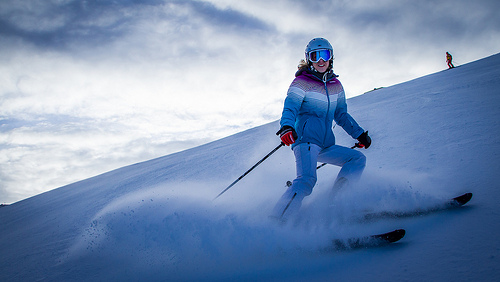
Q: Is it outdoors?
A: Yes, it is outdoors.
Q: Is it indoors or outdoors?
A: It is outdoors.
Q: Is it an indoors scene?
A: No, it is outdoors.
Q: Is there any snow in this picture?
A: Yes, there is snow.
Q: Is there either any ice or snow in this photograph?
A: Yes, there is snow.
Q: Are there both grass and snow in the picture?
A: No, there is snow but no grass.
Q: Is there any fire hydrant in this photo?
A: No, there are no fire hydrants.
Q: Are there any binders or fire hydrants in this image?
A: No, there are no fire hydrants or binders.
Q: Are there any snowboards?
A: No, there are no snowboards.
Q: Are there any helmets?
A: Yes, there is a helmet.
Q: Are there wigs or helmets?
A: Yes, there is a helmet.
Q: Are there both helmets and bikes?
A: No, there is a helmet but no bikes.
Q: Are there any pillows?
A: No, there are no pillows.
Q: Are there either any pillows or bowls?
A: No, there are no pillows or bowls.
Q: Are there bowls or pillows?
A: No, there are no pillows or bowls.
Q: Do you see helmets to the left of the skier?
A: Yes, there is a helmet to the left of the skier.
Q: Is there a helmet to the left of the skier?
A: Yes, there is a helmet to the left of the skier.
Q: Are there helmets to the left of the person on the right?
A: Yes, there is a helmet to the left of the skier.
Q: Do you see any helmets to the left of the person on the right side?
A: Yes, there is a helmet to the left of the skier.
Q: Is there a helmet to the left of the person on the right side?
A: Yes, there is a helmet to the left of the skier.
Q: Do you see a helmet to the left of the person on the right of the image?
A: Yes, there is a helmet to the left of the skier.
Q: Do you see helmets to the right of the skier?
A: No, the helmet is to the left of the skier.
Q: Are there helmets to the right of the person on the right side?
A: No, the helmet is to the left of the skier.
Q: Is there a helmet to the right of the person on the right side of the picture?
A: No, the helmet is to the left of the skier.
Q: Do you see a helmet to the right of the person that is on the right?
A: No, the helmet is to the left of the skier.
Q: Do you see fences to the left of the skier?
A: No, there is a helmet to the left of the skier.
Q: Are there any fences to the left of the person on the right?
A: No, there is a helmet to the left of the skier.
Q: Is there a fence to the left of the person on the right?
A: No, there is a helmet to the left of the skier.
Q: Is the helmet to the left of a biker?
A: No, the helmet is to the left of a skier.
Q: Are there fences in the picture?
A: No, there are no fences.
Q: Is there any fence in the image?
A: No, there are no fences.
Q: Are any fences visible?
A: No, there are no fences.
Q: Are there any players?
A: No, there are no players.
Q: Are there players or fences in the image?
A: No, there are no players or fences.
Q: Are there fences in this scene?
A: No, there are no fences.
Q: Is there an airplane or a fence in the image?
A: No, there are no fences or airplanes.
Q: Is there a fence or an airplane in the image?
A: No, there are no fences or airplanes.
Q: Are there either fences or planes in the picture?
A: No, there are no fences or planes.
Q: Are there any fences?
A: No, there are no fences.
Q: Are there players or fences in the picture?
A: No, there are no fences or players.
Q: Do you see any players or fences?
A: No, there are no fences or players.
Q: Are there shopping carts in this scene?
A: No, there are no shopping carts.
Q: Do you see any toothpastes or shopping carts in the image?
A: No, there are no shopping carts or toothpastes.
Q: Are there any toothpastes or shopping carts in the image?
A: No, there are no shopping carts or toothpastes.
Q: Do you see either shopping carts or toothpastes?
A: No, there are no shopping carts or toothpastes.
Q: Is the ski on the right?
A: Yes, the ski is on the right of the image.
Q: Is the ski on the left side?
A: No, the ski is on the right of the image.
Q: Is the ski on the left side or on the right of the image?
A: The ski is on the right of the image.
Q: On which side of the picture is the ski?
A: The ski is on the right of the image.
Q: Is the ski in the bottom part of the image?
A: Yes, the ski is in the bottom of the image.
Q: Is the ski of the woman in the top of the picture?
A: No, the ski is in the bottom of the image.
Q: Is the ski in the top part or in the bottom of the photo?
A: The ski is in the bottom of the image.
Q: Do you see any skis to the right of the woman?
A: Yes, there is a ski to the right of the woman.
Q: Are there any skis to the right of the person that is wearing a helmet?
A: Yes, there is a ski to the right of the woman.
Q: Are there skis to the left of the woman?
A: No, the ski is to the right of the woman.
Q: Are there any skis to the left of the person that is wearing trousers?
A: No, the ski is to the right of the woman.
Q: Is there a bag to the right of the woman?
A: No, there is a ski to the right of the woman.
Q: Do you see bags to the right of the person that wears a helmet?
A: No, there is a ski to the right of the woman.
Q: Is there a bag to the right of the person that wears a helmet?
A: No, there is a ski to the right of the woman.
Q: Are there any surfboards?
A: No, there are no surfboards.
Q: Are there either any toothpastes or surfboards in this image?
A: No, there are no surfboards or toothpastes.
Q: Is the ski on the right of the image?
A: Yes, the ski is on the right of the image.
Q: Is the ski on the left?
A: No, the ski is on the right of the image.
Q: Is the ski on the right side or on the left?
A: The ski is on the right of the image.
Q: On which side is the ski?
A: The ski is on the right of the image.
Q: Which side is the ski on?
A: The ski is on the right of the image.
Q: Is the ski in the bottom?
A: Yes, the ski is in the bottom of the image.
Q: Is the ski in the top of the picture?
A: No, the ski is in the bottom of the image.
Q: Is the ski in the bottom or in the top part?
A: The ski is in the bottom of the image.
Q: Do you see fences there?
A: No, there are no fences.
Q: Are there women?
A: Yes, there is a woman.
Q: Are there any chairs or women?
A: Yes, there is a woman.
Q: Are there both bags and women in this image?
A: No, there is a woman but no bags.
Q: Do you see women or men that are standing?
A: Yes, the woman is standing.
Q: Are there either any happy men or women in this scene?
A: Yes, there is a happy woman.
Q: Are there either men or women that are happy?
A: Yes, the woman is happy.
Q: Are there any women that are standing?
A: Yes, there is a woman that is standing.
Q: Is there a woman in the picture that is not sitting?
A: Yes, there is a woman that is standing.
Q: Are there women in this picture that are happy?
A: Yes, there is a happy woman.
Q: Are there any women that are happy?
A: Yes, there is a woman that is happy.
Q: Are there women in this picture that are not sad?
A: Yes, there is a happy woman.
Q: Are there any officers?
A: No, there are no officers.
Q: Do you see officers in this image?
A: No, there are no officers.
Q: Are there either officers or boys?
A: No, there are no officers or boys.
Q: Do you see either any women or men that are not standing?
A: No, there is a woman but she is standing.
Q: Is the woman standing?
A: Yes, the woman is standing.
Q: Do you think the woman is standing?
A: Yes, the woman is standing.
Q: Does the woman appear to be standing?
A: Yes, the woman is standing.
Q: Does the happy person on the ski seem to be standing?
A: Yes, the woman is standing.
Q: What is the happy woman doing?
A: The woman is standing.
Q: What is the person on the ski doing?
A: The woman is standing.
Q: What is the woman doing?
A: The woman is standing.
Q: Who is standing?
A: The woman is standing.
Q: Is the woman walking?
A: No, the woman is standing.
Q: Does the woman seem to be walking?
A: No, the woman is standing.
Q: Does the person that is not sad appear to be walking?
A: No, the woman is standing.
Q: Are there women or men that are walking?
A: No, there is a woman but she is standing.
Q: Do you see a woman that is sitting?
A: No, there is a woman but she is standing.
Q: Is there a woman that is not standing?
A: No, there is a woman but she is standing.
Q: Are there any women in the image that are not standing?
A: No, there is a woman but she is standing.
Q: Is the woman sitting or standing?
A: The woman is standing.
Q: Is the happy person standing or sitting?
A: The woman is standing.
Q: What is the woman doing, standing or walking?
A: The woman is standing.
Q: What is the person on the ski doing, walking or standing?
A: The woman is standing.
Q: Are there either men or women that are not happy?
A: No, there is a woman but she is happy.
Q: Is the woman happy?
A: Yes, the woman is happy.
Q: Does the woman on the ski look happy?
A: Yes, the woman is happy.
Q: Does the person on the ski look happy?
A: Yes, the woman is happy.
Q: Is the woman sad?
A: No, the woman is happy.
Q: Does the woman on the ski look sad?
A: No, the woman is happy.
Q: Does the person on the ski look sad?
A: No, the woman is happy.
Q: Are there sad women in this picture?
A: No, there is a woman but she is happy.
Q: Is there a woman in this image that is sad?
A: No, there is a woman but she is happy.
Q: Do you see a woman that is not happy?
A: No, there is a woman but she is happy.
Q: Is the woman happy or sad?
A: The woman is happy.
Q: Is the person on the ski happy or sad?
A: The woman is happy.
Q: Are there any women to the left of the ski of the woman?
A: Yes, there is a woman to the left of the ski.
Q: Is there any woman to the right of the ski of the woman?
A: No, the woman is to the left of the ski.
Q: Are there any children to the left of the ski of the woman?
A: No, there is a woman to the left of the ski.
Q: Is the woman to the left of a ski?
A: Yes, the woman is to the left of a ski.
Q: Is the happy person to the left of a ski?
A: Yes, the woman is to the left of a ski.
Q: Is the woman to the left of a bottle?
A: No, the woman is to the left of a ski.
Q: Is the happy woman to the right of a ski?
A: No, the woman is to the left of a ski.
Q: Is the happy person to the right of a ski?
A: No, the woman is to the left of a ski.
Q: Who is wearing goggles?
A: The woman is wearing goggles.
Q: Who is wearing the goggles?
A: The woman is wearing goggles.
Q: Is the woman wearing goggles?
A: Yes, the woman is wearing goggles.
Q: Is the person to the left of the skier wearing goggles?
A: Yes, the woman is wearing goggles.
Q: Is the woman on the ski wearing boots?
A: No, the woman is wearing goggles.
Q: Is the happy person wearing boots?
A: No, the woman is wearing goggles.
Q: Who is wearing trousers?
A: The woman is wearing trousers.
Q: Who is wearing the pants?
A: The woman is wearing trousers.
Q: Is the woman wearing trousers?
A: Yes, the woman is wearing trousers.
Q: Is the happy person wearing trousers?
A: Yes, the woman is wearing trousers.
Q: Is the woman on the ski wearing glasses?
A: No, the woman is wearing trousers.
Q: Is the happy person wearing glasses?
A: No, the woman is wearing trousers.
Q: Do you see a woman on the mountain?
A: Yes, there is a woman on the mountain.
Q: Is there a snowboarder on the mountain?
A: No, there is a woman on the mountain.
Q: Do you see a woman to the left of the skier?
A: Yes, there is a woman to the left of the skier.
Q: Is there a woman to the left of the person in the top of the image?
A: Yes, there is a woman to the left of the skier.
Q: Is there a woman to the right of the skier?
A: No, the woman is to the left of the skier.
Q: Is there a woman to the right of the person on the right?
A: No, the woman is to the left of the skier.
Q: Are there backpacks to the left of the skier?
A: No, there is a woman to the left of the skier.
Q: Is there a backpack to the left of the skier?
A: No, there is a woman to the left of the skier.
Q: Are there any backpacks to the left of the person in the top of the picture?
A: No, there is a woman to the left of the skier.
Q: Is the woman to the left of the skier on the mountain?
A: Yes, the woman is to the left of the skier.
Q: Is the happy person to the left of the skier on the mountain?
A: Yes, the woman is to the left of the skier.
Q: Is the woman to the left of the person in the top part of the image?
A: Yes, the woman is to the left of the skier.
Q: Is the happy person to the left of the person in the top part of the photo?
A: Yes, the woman is to the left of the skier.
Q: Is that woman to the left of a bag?
A: No, the woman is to the left of the skier.